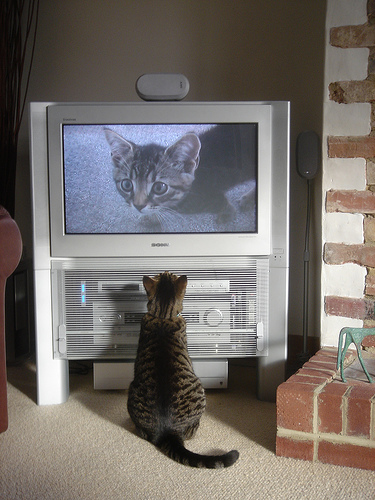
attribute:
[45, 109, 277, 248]
television — grey, on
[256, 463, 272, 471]
carpet — white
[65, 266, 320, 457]
couch — red, side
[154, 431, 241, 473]
cat tail — mostly black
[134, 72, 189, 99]
speaker — long